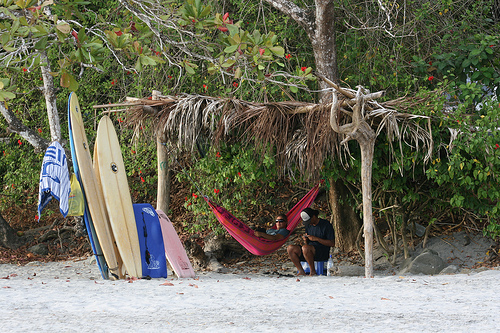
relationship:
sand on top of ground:
[0, 252, 499, 332] [0, 220, 498, 332]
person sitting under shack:
[284, 206, 337, 276] [89, 68, 438, 276]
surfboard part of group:
[95, 109, 140, 279] [59, 89, 199, 281]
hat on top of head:
[295, 206, 321, 223] [299, 205, 321, 226]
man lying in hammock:
[244, 211, 291, 258] [169, 143, 326, 255]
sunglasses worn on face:
[272, 219, 287, 224] [270, 209, 289, 231]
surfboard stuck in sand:
[95, 109, 140, 279] [0, 252, 499, 332]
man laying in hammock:
[244, 211, 291, 258] [169, 143, 326, 255]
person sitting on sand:
[284, 206, 337, 276] [0, 252, 499, 332]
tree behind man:
[255, 0, 370, 263] [244, 211, 291, 258]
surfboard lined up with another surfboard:
[95, 109, 140, 279] [68, 91, 123, 279]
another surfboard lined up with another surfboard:
[68, 91, 121, 281] [68, 91, 123, 279]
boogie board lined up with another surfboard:
[150, 206, 198, 278] [68, 91, 123, 279]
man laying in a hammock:
[244, 211, 291, 258] [169, 143, 326, 255]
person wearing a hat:
[284, 206, 337, 276] [295, 206, 321, 223]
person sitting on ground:
[284, 206, 337, 276] [0, 220, 498, 332]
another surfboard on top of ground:
[68, 91, 121, 281] [0, 220, 498, 332]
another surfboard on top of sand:
[68, 91, 121, 281] [0, 252, 499, 332]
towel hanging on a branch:
[32, 137, 72, 219] [1, 104, 74, 172]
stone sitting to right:
[404, 247, 446, 277] [339, 0, 499, 332]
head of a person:
[299, 205, 321, 226] [284, 206, 337, 276]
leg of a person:
[299, 240, 328, 276] [284, 206, 337, 276]